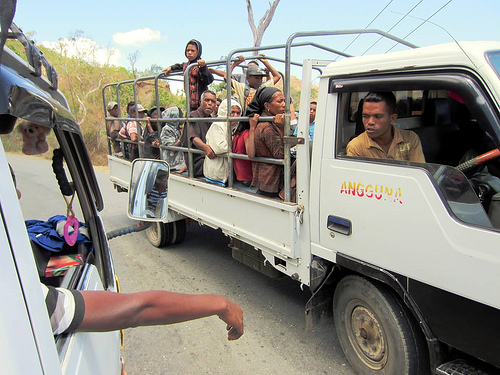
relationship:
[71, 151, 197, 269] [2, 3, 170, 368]
mirror on vehicle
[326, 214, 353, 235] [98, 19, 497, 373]
door handle on truck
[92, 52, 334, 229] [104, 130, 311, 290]
ribs cover truck bed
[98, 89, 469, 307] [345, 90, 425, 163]
truck carrying driver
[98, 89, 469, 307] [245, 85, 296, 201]
truck carrying person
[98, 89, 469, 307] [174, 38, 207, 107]
truck carrying passengers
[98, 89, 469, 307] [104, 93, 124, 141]
truck carrying passengers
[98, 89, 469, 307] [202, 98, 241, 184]
truck carrying person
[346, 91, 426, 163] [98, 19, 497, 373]
driver in truck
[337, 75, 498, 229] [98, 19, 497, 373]
window in truck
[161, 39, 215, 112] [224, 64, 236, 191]
boy holding bar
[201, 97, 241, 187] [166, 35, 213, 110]
person wearing jacket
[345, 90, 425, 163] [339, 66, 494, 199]
driver looking out window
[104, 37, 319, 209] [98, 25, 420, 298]
people in back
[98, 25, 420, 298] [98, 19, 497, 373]
back of truck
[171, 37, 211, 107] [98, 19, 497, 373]
boy standing on truck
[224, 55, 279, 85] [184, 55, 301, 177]
arms hanging on to bar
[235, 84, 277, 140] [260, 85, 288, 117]
scarf on her head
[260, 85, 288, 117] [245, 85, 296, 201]
head of person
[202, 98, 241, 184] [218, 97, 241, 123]
person with hood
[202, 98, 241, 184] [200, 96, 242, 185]
person with jacket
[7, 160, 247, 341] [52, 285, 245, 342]
person has an arm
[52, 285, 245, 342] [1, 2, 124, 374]
arm hangs out of vehicle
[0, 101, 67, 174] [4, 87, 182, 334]
bear hangs inside truck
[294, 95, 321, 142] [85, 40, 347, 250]
boy in back of back truck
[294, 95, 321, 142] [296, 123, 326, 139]
boy wearing blue shirt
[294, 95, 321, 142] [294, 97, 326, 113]
boy has black hair